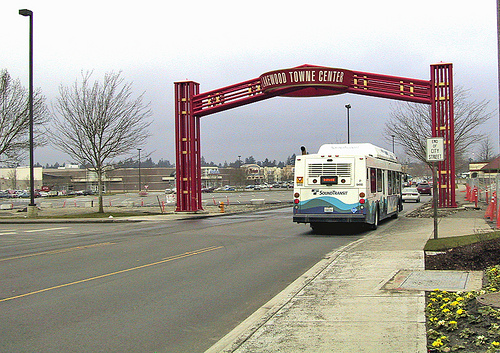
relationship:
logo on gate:
[254, 67, 350, 89] [171, 64, 458, 211]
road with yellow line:
[1, 216, 331, 352] [0, 243, 225, 302]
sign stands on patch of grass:
[423, 136, 446, 167] [424, 231, 498, 251]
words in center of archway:
[258, 70, 345, 85] [141, 49, 482, 218]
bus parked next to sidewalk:
[292, 140, 399, 230] [223, 213, 422, 345]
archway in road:
[174, 57, 458, 217] [2, 192, 431, 350]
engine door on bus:
[303, 157, 356, 188] [287, 141, 406, 233]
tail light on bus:
[357, 190, 367, 208] [306, 127, 381, 217]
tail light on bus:
[291, 191, 301, 206] [306, 127, 381, 217]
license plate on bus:
[320, 205, 336, 217] [277, 122, 419, 249]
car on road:
[402, 187, 419, 200] [2, 192, 431, 350]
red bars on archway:
[425, 63, 463, 213] [170, 61, 459, 215]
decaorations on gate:
[176, 86, 190, 201] [158, 49, 475, 238]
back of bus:
[291, 154, 372, 219] [290, 141, 408, 233]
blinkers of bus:
[357, 189, 368, 213] [290, 141, 408, 233]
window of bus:
[366, 164, 377, 196] [290, 141, 408, 233]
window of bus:
[375, 166, 383, 196] [290, 141, 408, 233]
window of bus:
[386, 170, 399, 198] [290, 141, 408, 233]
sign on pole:
[423, 136, 445, 165] [428, 161, 442, 240]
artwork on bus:
[294, 191, 374, 220] [285, 100, 428, 263]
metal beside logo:
[171, 77, 206, 214] [254, 67, 344, 90]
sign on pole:
[423, 136, 445, 165] [425, 171, 444, 240]